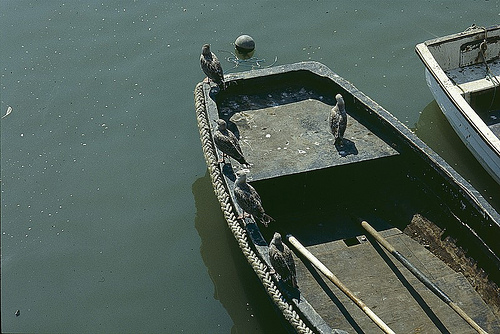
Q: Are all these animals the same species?
A: Yes, all the animals are birds.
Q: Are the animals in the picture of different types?
A: No, all the animals are birds.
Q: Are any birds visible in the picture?
A: Yes, there is a bird.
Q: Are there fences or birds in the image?
A: Yes, there is a bird.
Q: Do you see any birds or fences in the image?
A: Yes, there is a bird.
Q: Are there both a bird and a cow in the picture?
A: No, there is a bird but no cows.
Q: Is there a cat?
A: No, there are no cats.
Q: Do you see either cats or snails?
A: No, there are no cats or snails.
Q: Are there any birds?
A: Yes, there is a bird.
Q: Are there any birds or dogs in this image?
A: Yes, there is a bird.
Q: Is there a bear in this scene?
A: No, there are no bears.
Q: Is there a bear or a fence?
A: No, there are no bears or fences.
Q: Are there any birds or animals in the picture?
A: Yes, there is a bird.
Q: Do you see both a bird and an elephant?
A: No, there is a bird but no elephants.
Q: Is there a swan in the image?
A: No, there are no swans.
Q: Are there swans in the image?
A: No, there are no swans.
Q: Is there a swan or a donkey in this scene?
A: No, there are no swans or donkeys.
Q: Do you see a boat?
A: Yes, there is a boat.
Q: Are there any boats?
A: Yes, there is a boat.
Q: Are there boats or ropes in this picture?
A: Yes, there is a boat.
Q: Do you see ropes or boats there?
A: Yes, there is a boat.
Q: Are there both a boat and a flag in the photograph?
A: No, there is a boat but no flags.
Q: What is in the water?
A: The boat is in the water.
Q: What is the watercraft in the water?
A: The watercraft is a boat.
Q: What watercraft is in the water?
A: The watercraft is a boat.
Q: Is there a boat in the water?
A: Yes, there is a boat in the water.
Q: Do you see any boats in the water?
A: Yes, there is a boat in the water.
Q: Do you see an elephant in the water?
A: No, there is a boat in the water.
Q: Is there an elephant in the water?
A: No, there is a boat in the water.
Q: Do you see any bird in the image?
A: Yes, there is a bird.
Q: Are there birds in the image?
A: Yes, there is a bird.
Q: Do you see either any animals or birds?
A: Yes, there is a bird.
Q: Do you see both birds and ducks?
A: No, there is a bird but no ducks.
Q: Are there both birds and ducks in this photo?
A: No, there is a bird but no ducks.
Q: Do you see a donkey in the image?
A: No, there are no donkeys.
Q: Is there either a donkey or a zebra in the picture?
A: No, there are no donkeys or zebras.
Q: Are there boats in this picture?
A: Yes, there is a boat.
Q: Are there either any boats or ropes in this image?
A: Yes, there is a boat.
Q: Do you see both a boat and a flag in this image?
A: No, there is a boat but no flags.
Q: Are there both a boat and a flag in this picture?
A: No, there is a boat but no flags.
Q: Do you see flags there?
A: No, there are no flags.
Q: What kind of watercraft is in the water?
A: The watercraft is a boat.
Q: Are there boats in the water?
A: Yes, there is a boat in the water.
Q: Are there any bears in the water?
A: No, there is a boat in the water.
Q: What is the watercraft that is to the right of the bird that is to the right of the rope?
A: The watercraft is a boat.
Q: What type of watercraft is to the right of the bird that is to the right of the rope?
A: The watercraft is a boat.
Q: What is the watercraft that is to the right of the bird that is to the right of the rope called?
A: The watercraft is a boat.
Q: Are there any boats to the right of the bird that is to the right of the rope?
A: Yes, there is a boat to the right of the bird.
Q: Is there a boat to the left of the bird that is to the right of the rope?
A: No, the boat is to the right of the bird.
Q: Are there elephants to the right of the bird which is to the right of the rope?
A: No, there is a boat to the right of the bird.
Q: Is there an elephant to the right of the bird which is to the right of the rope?
A: No, there is a boat to the right of the bird.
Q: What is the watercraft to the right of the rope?
A: The watercraft is a boat.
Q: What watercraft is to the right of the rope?
A: The watercraft is a boat.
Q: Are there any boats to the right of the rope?
A: Yes, there is a boat to the right of the rope.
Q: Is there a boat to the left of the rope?
A: No, the boat is to the right of the rope.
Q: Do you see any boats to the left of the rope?
A: No, the boat is to the right of the rope.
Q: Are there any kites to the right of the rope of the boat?
A: No, there is a boat to the right of the rope.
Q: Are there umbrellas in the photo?
A: No, there are no umbrellas.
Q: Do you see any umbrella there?
A: No, there are no umbrellas.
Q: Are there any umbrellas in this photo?
A: No, there are no umbrellas.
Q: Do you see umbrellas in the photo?
A: No, there are no umbrellas.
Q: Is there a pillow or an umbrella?
A: No, there are no umbrellas or pillows.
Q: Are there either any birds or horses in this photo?
A: Yes, there is a bird.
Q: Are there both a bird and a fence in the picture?
A: No, there is a bird but no fences.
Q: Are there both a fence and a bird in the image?
A: No, there is a bird but no fences.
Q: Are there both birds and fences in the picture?
A: No, there is a bird but no fences.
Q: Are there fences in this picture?
A: No, there are no fences.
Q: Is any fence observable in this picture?
A: No, there are no fences.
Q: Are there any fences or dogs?
A: No, there are no fences or dogs.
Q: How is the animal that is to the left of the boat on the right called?
A: The animal is a bird.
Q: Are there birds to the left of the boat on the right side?
A: Yes, there is a bird to the left of the boat.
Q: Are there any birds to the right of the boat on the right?
A: No, the bird is to the left of the boat.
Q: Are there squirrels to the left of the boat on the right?
A: No, there is a bird to the left of the boat.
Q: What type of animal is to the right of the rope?
A: The animal is a bird.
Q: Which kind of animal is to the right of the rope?
A: The animal is a bird.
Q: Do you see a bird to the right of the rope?
A: Yes, there is a bird to the right of the rope.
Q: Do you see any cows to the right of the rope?
A: No, there is a bird to the right of the rope.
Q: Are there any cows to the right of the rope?
A: No, there is a bird to the right of the rope.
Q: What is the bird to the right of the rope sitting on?
A: The bird is sitting on the boat.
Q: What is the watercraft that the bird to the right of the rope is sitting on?
A: The watercraft is a boat.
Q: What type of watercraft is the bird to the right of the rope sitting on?
A: The bird is sitting on the boat.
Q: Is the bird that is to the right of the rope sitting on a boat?
A: Yes, the bird is sitting on a boat.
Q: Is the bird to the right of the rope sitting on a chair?
A: No, the bird is sitting on a boat.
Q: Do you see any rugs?
A: No, there are no rugs.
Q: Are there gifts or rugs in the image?
A: No, there are no rugs or gifts.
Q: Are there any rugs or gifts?
A: No, there are no rugs or gifts.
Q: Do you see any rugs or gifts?
A: No, there are no rugs or gifts.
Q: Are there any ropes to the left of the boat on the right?
A: Yes, there is a rope to the left of the boat.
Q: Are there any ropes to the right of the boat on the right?
A: No, the rope is to the left of the boat.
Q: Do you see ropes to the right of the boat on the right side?
A: No, the rope is to the left of the boat.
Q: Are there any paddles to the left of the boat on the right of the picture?
A: No, there is a rope to the left of the boat.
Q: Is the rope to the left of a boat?
A: Yes, the rope is to the left of a boat.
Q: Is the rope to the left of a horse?
A: No, the rope is to the left of a boat.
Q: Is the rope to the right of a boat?
A: No, the rope is to the left of a boat.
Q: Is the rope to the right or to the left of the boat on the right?
A: The rope is to the left of the boat.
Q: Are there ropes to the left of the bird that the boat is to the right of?
A: Yes, there is a rope to the left of the bird.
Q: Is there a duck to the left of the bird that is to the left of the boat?
A: No, there is a rope to the left of the bird.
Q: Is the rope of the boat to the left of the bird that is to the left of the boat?
A: Yes, the rope is to the left of the bird.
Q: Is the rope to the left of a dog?
A: No, the rope is to the left of the bird.